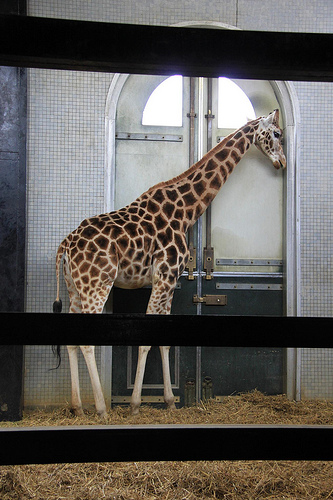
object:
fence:
[0, 10, 333, 465]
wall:
[25, 0, 333, 405]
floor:
[0, 397, 333, 499]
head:
[252, 102, 288, 172]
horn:
[270, 107, 282, 125]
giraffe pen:
[0, 0, 333, 498]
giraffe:
[50, 106, 288, 413]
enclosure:
[12, 18, 326, 495]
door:
[108, 17, 286, 399]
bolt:
[193, 290, 229, 306]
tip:
[48, 296, 63, 370]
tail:
[48, 240, 66, 374]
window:
[117, 72, 189, 136]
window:
[207, 74, 273, 129]